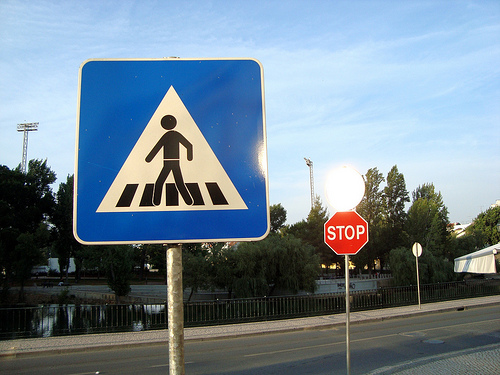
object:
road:
[0, 304, 500, 375]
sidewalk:
[0, 294, 500, 357]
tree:
[212, 232, 321, 300]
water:
[45, 297, 212, 339]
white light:
[318, 162, 365, 210]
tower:
[304, 157, 316, 213]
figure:
[145, 114, 194, 206]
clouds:
[259, 21, 500, 67]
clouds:
[264, 100, 397, 137]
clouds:
[270, 173, 309, 213]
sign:
[72, 58, 270, 247]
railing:
[2, 275, 499, 336]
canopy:
[452, 240, 499, 273]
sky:
[1, 0, 498, 222]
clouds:
[0, 0, 70, 66]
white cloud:
[460, 145, 495, 179]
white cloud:
[0, 141, 74, 154]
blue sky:
[249, 0, 428, 39]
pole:
[165, 245, 187, 375]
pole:
[345, 255, 352, 375]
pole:
[416, 257, 422, 309]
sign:
[412, 241, 423, 257]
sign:
[324, 210, 369, 255]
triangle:
[95, 83, 250, 214]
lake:
[0, 297, 480, 342]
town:
[3, 240, 398, 292]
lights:
[28, 121, 39, 131]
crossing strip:
[115, 184, 138, 207]